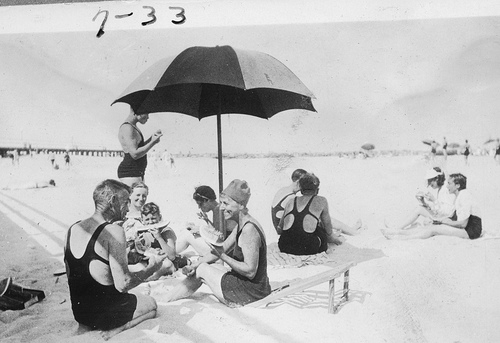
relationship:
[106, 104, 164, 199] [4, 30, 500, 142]
person in sun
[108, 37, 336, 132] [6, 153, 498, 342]
umbrella on beach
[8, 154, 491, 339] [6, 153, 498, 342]
sand on beach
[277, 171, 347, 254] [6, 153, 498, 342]
women on beach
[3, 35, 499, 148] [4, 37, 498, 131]
sky in back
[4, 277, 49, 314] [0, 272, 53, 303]
black beach cloth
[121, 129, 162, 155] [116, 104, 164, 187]
arm of person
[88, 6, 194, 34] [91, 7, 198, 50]
date in ink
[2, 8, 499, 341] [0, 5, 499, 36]
photo with border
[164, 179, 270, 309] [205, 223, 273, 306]
lady in suit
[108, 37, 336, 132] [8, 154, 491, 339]
umbrella in sand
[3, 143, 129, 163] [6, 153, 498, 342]
pier at beach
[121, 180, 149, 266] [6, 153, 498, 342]
woman on beach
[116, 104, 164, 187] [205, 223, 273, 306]
person in suit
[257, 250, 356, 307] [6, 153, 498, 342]
chair at beach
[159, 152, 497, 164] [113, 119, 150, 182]
swimming a costume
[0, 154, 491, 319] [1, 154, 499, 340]
sandy a area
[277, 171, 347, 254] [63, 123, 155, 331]
women wearing suits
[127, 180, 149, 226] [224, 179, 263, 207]
woman wearing cap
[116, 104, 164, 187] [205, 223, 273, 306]
person wearing suit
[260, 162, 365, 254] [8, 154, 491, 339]
women on sand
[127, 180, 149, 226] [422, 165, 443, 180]
woman wearing visor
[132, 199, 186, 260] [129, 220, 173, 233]
boy eating melon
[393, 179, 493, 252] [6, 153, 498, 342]
sitting on beach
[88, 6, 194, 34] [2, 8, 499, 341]
date on photo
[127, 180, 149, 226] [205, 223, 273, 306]
woman wearing suit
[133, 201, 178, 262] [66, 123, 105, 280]
boy have backs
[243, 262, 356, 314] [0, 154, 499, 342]
chair lying on sand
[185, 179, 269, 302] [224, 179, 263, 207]
lady wearing a cap